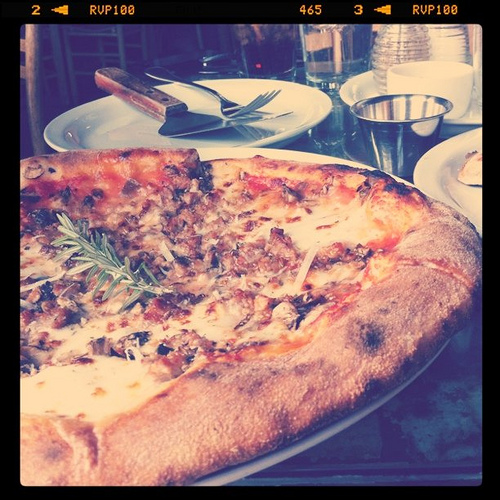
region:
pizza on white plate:
[19, 142, 492, 489]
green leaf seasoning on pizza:
[35, 206, 182, 336]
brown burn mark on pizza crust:
[347, 315, 392, 355]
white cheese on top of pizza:
[194, 303, 241, 338]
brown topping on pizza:
[83, 325, 200, 369]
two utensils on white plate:
[81, 54, 303, 145]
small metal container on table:
[331, 87, 453, 180]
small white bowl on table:
[374, 51, 479, 119]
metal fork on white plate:
[145, 59, 285, 118]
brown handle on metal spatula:
[82, 60, 191, 120]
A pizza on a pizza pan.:
[13, 131, 489, 497]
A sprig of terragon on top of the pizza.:
[46, 210, 176, 310]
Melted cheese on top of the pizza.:
[0, 175, 418, 420]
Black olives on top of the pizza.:
[12, 180, 317, 386]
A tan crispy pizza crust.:
[22, 198, 483, 490]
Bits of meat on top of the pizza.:
[11, 167, 352, 380]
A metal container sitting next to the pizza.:
[350, 93, 453, 182]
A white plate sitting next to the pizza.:
[40, 79, 331, 151]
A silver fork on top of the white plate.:
[140, 65, 281, 116]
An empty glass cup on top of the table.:
[300, 21, 347, 93]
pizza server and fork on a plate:
[38, 50, 337, 142]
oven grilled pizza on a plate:
[0, 142, 481, 492]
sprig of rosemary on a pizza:
[41, 210, 193, 331]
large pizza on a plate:
[19, 138, 481, 485]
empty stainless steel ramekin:
[348, 79, 447, 170]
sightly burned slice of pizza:
[198, 142, 435, 282]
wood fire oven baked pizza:
[21, 145, 479, 481]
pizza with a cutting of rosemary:
[18, 147, 481, 488]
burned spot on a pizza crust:
[331, 313, 408, 368]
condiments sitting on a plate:
[340, 20, 499, 127]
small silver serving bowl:
[349, 91, 455, 174]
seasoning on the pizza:
[57, 211, 160, 302]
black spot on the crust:
[351, 318, 380, 352]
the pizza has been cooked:
[16, 147, 478, 486]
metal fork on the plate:
[145, 68, 282, 118]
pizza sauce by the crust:
[28, 171, 163, 191]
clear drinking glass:
[299, 23, 369, 89]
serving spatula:
[95, 68, 291, 137]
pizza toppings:
[21, 176, 343, 411]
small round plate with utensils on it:
[43, 80, 332, 147]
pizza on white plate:
[21, 139, 488, 481]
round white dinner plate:
[37, 71, 337, 152]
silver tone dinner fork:
[139, 60, 284, 120]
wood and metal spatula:
[91, 63, 294, 136]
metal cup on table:
[349, 90, 455, 190]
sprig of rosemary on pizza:
[47, 208, 174, 308]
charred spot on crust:
[345, 314, 393, 363]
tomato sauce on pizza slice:
[16, 169, 177, 221]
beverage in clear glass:
[230, 25, 304, 82]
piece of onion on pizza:
[290, 238, 323, 298]